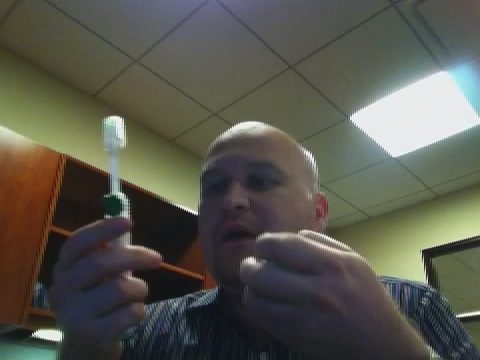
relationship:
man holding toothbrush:
[44, 119, 477, 360] [44, 118, 479, 358]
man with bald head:
[44, 119, 477, 360] [205, 121, 320, 182]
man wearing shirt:
[44, 119, 477, 360] [105, 268, 477, 358]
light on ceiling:
[349, 64, 480, 160] [25, 13, 478, 172]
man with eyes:
[44, 119, 477, 360] [172, 173, 282, 194]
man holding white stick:
[44, 119, 477, 360] [100, 113, 138, 341]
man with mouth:
[44, 119, 477, 360] [213, 216, 261, 247]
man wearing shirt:
[44, 119, 477, 360] [119, 276, 478, 358]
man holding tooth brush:
[44, 119, 477, 360] [99, 112, 134, 284]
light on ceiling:
[349, 64, 480, 160] [1, 0, 475, 231]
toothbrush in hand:
[100, 114, 132, 279] [46, 214, 163, 350]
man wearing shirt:
[44, 119, 477, 360] [116, 269, 449, 357]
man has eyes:
[44, 119, 477, 360] [195, 170, 299, 194]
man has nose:
[44, 119, 477, 360] [217, 176, 248, 212]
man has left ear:
[44, 119, 477, 360] [309, 192, 328, 231]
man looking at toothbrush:
[44, 119, 477, 360] [100, 114, 132, 279]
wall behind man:
[328, 184, 478, 286] [44, 119, 477, 360]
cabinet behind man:
[1, 123, 217, 329] [44, 119, 477, 360]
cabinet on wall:
[1, 123, 217, 329] [0, 45, 219, 230]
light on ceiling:
[349, 64, 477, 173] [2, 0, 424, 216]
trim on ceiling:
[206, 0, 298, 75] [138, 11, 386, 94]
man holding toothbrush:
[44, 119, 477, 360] [104, 113, 134, 279]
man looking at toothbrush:
[44, 119, 477, 360] [98, 109, 137, 302]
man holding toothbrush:
[62, 119, 478, 356] [78, 102, 163, 244]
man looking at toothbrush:
[44, 119, 477, 360] [101, 113, 140, 338]